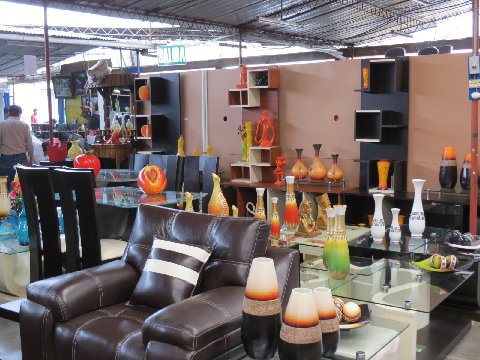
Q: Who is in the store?
A: A man.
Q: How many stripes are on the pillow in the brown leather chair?
A: Two.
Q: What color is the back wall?
A: Brown / beige.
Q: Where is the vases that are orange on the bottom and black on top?
A: Against the back wall.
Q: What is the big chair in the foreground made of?
A: Leather.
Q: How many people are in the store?
A: One.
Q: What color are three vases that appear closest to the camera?
A: White, orange, brown, and black.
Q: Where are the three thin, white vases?
A: Toward the middle on the right hand side of the photo.